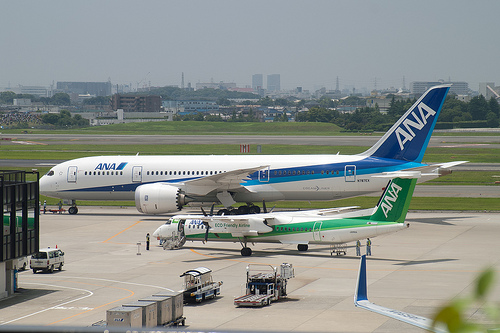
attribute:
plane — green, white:
[139, 162, 452, 265]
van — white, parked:
[27, 237, 71, 285]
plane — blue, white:
[16, 78, 458, 213]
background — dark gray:
[0, 0, 492, 143]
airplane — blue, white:
[318, 239, 446, 331]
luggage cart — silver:
[227, 250, 300, 314]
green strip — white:
[163, 201, 405, 260]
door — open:
[175, 217, 194, 245]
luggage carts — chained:
[112, 289, 184, 318]